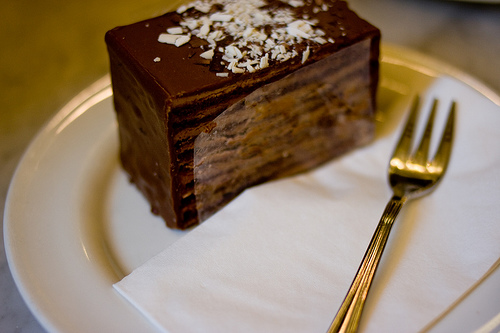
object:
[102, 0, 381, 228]
cake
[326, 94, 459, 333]
fork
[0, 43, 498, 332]
plate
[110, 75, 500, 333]
napkin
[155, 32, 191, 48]
sprinkles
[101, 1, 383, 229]
chocolate coating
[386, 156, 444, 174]
light reflected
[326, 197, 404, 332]
handle of fork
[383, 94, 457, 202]
tines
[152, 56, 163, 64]
sprinkle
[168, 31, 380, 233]
layers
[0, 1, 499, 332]
table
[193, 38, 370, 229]
paper